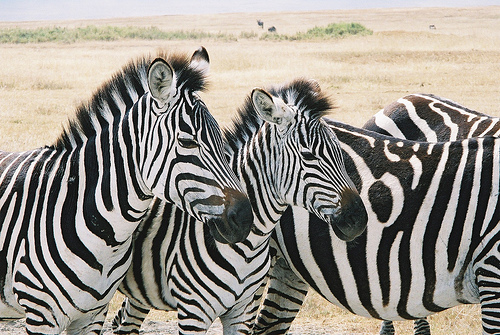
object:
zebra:
[256, 93, 499, 335]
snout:
[336, 191, 368, 230]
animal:
[0, 44, 256, 335]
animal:
[108, 75, 369, 334]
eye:
[300, 151, 321, 161]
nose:
[225, 193, 255, 227]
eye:
[179, 137, 200, 150]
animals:
[250, 18, 277, 34]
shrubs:
[0, 18, 259, 45]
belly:
[270, 206, 471, 324]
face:
[141, 95, 253, 245]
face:
[273, 118, 368, 243]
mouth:
[331, 223, 367, 242]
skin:
[291, 119, 328, 148]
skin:
[407, 189, 433, 318]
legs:
[176, 311, 256, 334]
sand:
[0, 45, 500, 96]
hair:
[91, 56, 141, 94]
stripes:
[446, 136, 500, 240]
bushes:
[292, 21, 374, 40]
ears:
[188, 45, 210, 77]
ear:
[143, 58, 178, 109]